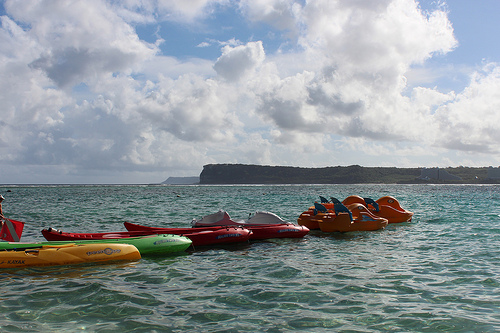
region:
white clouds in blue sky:
[16, 15, 113, 102]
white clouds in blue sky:
[121, 20, 202, 82]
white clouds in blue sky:
[200, 19, 276, 75]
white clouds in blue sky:
[266, 7, 351, 88]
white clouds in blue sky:
[333, 15, 399, 66]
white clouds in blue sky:
[402, 35, 467, 122]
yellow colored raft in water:
[32, 235, 134, 277]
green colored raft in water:
[148, 225, 189, 256]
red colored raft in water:
[190, 206, 240, 241]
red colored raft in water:
[255, 182, 305, 253]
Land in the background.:
[196, 161, 498, 186]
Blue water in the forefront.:
[1, 184, 498, 331]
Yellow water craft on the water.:
[1, 236, 146, 271]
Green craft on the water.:
[68, 233, 195, 253]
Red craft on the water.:
[155, 220, 247, 250]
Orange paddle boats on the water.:
[300, 190, 412, 240]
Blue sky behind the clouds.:
[152, 19, 284, 53]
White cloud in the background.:
[315, 6, 450, 76]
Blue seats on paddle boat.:
[315, 195, 350, 211]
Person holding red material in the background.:
[0, 190, 21, 242]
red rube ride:
[303, 193, 387, 244]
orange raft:
[12, 222, 143, 277]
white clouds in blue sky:
[22, 9, 90, 71]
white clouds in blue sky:
[32, 78, 100, 135]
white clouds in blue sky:
[230, 35, 320, 96]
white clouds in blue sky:
[297, 15, 384, 85]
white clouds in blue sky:
[359, 16, 440, 80]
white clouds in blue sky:
[339, 15, 424, 120]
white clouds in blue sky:
[446, 83, 496, 140]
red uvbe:
[203, 199, 303, 270]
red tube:
[300, 191, 364, 256]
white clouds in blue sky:
[32, 33, 122, 85]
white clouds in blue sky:
[12, 66, 72, 110]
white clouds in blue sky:
[120, 31, 185, 65]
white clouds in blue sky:
[179, 26, 260, 66]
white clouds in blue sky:
[373, 79, 451, 121]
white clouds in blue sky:
[213, 102, 305, 143]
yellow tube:
[33, 231, 145, 273]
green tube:
[147, 236, 187, 260]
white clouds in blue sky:
[65, 69, 150, 126]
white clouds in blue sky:
[90, 109, 155, 167]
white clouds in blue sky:
[176, 75, 250, 136]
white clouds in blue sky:
[256, 93, 333, 135]